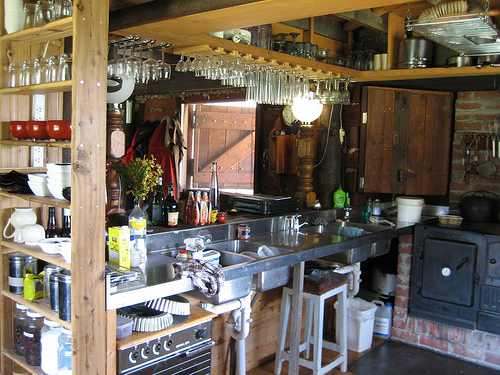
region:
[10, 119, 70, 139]
three red dishes on shelf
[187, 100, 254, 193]
open wooden window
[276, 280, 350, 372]
white, wooden stool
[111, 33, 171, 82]
wine glasses hanging from wooden ceiling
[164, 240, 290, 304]
deep, metal, silver washsink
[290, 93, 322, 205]
crafted, wooden lamp that is turned on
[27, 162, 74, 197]
small, white dishes shelf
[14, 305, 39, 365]
Clear, glass jar on bottom of shelf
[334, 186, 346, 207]
green soap dispenser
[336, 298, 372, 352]
white trashcan on the floor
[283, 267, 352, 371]
a white and brown stool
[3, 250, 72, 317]
canisters on the shelf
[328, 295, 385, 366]
white waste basket on the floor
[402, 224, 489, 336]
cast iron oven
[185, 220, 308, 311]
stainless steel sink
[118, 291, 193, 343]
silver pie pans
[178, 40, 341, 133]
wine glasses hanging from rack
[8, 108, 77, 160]
red bowls on the shelf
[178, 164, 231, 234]
wine bottles on the counter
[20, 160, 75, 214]
white bowls on the shelf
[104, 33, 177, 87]
wine glasses hanging from a rack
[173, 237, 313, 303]
stainless stell double sinks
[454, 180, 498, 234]
cast iron pot of the stove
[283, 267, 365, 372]
bar stool pushed under sink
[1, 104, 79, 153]
row of red bowls on a shelf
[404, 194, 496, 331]
a wood burning stove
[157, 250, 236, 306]
a towel left on the counter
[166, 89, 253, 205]
a wooden door is open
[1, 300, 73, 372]
canisters of dry golds on the shelf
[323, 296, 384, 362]
a white plastic trash can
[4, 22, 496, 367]
This is a kitchen scene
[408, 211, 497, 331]
A wood fired oven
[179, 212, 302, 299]
A kitchen sink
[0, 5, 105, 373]
A wooden shelf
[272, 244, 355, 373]
A stool is under the sink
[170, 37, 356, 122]
A rack for glasses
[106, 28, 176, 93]
Wine glasses are hanging on this rack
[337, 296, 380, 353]
A waste basket is on the floor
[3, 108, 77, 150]
Red bowls are on the shelf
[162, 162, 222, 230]
Bottles are on the bar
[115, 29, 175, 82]
wine glasses hanging from the ceiling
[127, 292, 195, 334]
fluted baking pans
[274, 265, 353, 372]
padded stool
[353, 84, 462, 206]
rough wooden cupboard door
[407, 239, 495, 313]
oven door with built in thermostat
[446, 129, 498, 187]
kitchen utensils hanging on wall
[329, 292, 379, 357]
wastebasket lined with garbage bag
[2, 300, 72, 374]
gallon jars storing food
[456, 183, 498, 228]
cast iron dutch oven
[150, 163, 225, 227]
bottles of alcoholic drinks